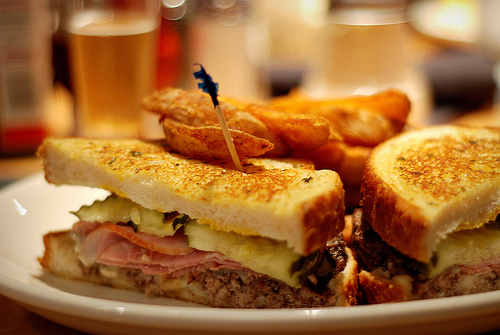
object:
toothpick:
[192, 60, 247, 172]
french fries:
[142, 88, 292, 158]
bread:
[37, 135, 357, 306]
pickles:
[133, 213, 189, 237]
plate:
[0, 169, 498, 335]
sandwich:
[37, 136, 360, 309]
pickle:
[67, 194, 165, 229]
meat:
[97, 240, 244, 277]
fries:
[141, 86, 291, 156]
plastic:
[190, 63, 220, 108]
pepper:
[300, 176, 313, 185]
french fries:
[243, 103, 330, 151]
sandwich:
[360, 124, 500, 304]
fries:
[248, 156, 316, 169]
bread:
[359, 123, 498, 302]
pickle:
[186, 218, 349, 288]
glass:
[65, 0, 160, 138]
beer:
[70, 20, 157, 138]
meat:
[95, 220, 198, 255]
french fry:
[270, 87, 411, 147]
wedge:
[35, 62, 347, 256]